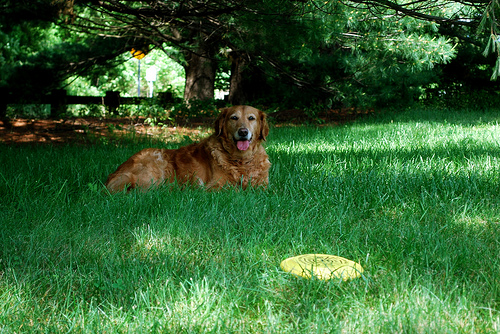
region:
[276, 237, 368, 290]
yellow frisbee on grass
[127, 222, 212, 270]
white spot on green grass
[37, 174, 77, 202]
single blade of green grass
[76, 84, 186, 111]
long fence in background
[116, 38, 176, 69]
yellow road sign with post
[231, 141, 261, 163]
wagging tongue on dog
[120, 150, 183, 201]
white spot on dog's body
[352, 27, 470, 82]
long branch on tree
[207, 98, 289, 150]
floppy ears on dog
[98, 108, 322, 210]
large brown dog laying in field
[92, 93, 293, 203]
Dog is brown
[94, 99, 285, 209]
Dog is lying on a green grass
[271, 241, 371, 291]
Frisbee on the grass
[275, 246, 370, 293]
Frisbee is yellow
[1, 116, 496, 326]
Grass is green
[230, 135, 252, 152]
Tongue of dog is pink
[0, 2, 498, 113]
Trees are behind an open field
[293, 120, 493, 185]
Shadows casting on green grass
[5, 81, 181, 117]
Fence on background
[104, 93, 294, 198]
Dog is facing to the front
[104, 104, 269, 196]
the dog sits on the grass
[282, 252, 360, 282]
the frisbee is yellow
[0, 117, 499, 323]
the grass is lush and full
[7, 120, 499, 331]
the grass is green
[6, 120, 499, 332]
the sun comes through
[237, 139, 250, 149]
the dog has his tongue out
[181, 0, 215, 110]
the tree is in the background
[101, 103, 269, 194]
the dog is brown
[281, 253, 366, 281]
the frisbee is on the floor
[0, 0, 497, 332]
the scene takes place outdoors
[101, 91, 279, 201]
Dog sticking tongue out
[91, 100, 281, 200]
Dog has brown fur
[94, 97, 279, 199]
Fur of dog is furry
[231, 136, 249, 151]
Tongue is out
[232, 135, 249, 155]
Tongue is pink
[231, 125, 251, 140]
Snout is white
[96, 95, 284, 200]
Dog is laying on green grass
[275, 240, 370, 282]
Yellow frisbee on green grass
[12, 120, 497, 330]
Green grass on field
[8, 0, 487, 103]
Trees on the background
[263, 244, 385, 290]
yellow Frisbee in the grass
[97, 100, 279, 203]
dog reclined in the grass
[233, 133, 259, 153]
tongue of panting dog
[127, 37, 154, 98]
yellow sign on pole in distance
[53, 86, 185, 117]
short fence in the distance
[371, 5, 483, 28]
tree branches above grass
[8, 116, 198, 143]
patch of dirt beyond grass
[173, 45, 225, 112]
thick tree trunk in front of fence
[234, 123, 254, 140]
black nose on dog snout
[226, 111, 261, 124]
dogs dark eyes open